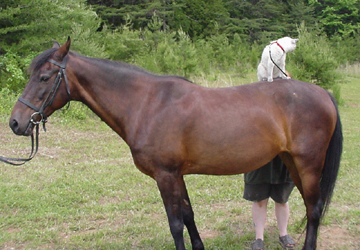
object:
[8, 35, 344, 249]
horse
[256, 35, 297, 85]
cat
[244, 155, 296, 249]
person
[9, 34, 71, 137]
head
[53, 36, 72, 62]
ear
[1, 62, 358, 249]
grass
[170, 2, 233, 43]
tree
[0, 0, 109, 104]
tree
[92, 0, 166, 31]
tree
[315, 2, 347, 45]
tree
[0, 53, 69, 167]
harness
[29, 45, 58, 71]
hair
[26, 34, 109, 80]
top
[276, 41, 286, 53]
collar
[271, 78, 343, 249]
hind quarters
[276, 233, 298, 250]
sandals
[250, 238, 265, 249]
sandals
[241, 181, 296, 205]
shorts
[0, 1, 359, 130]
background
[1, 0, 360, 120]
vegetation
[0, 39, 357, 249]
field